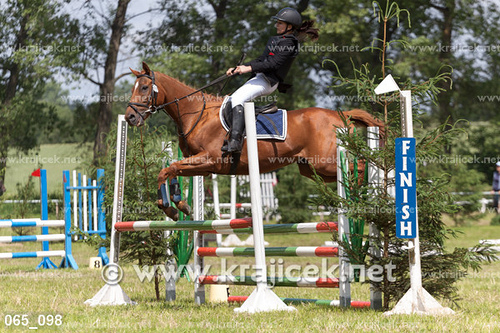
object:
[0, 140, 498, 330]
grass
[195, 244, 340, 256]
pole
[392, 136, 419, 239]
sign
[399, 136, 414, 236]
word